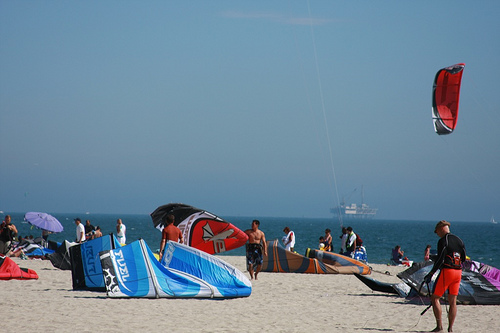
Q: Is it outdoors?
A: Yes, it is outdoors.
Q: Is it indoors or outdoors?
A: It is outdoors.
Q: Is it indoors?
A: No, it is outdoors.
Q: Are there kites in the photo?
A: Yes, there is a kite.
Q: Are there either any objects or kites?
A: Yes, there is a kite.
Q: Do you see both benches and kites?
A: No, there is a kite but no benches.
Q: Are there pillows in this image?
A: No, there are no pillows.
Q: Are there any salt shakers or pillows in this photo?
A: No, there are no pillows or salt shakers.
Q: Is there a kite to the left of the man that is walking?
A: Yes, there is a kite to the left of the man.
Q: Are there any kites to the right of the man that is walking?
A: No, the kite is to the left of the man.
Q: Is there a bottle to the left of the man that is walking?
A: No, there is a kite to the left of the man.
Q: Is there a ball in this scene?
A: No, there are no balls.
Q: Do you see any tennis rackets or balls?
A: No, there are no balls or tennis rackets.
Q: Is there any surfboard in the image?
A: No, there are no surfboards.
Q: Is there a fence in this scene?
A: No, there are no fences.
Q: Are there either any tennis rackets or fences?
A: No, there are no fences or tennis rackets.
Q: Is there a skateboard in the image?
A: No, there are no skateboards.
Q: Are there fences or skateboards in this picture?
A: No, there are no skateboards or fences.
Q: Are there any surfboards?
A: No, there are no surfboards.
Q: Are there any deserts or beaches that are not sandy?
A: No, there is a beach but it is sandy.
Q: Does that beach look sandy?
A: Yes, the beach is sandy.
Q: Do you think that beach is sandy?
A: Yes, the beach is sandy.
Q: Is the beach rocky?
A: No, the beach is sandy.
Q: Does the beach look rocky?
A: No, the beach is sandy.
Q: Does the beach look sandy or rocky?
A: The beach is sandy.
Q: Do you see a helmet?
A: No, there are no helmets.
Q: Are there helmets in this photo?
A: No, there are no helmets.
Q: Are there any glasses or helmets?
A: No, there are no helmets or glasses.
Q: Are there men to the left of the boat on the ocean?
A: Yes, there is a man to the left of the boat.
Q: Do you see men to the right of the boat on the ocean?
A: No, the man is to the left of the boat.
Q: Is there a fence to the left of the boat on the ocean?
A: No, there is a man to the left of the boat.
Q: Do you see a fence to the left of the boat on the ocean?
A: No, there is a man to the left of the boat.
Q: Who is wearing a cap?
A: The man is wearing a cap.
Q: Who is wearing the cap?
A: The man is wearing a cap.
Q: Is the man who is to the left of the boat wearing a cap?
A: Yes, the man is wearing a cap.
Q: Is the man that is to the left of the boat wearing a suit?
A: No, the man is wearing a cap.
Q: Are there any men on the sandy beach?
A: Yes, there is a man on the beach.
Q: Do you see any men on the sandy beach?
A: Yes, there is a man on the beach.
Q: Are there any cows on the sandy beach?
A: No, there is a man on the beach.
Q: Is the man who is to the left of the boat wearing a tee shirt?
A: Yes, the man is wearing a tee shirt.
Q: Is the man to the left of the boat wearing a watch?
A: No, the man is wearing a tee shirt.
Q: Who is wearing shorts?
A: The man is wearing shorts.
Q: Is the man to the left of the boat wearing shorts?
A: Yes, the man is wearing shorts.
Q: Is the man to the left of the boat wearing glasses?
A: No, the man is wearing shorts.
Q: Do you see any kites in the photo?
A: Yes, there is a kite.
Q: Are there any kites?
A: Yes, there is a kite.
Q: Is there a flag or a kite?
A: Yes, there is a kite.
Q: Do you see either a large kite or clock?
A: Yes, there is a large kite.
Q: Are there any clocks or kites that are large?
A: Yes, the kite is large.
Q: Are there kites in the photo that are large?
A: Yes, there is a large kite.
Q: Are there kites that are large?
A: Yes, there is a kite that is large.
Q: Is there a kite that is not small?
A: Yes, there is a large kite.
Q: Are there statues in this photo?
A: No, there are no statues.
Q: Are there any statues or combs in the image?
A: No, there are no statues or combs.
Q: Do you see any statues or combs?
A: No, there are no statues or combs.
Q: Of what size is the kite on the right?
A: The kite is large.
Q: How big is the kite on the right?
A: The kite is large.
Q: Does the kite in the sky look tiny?
A: No, the kite is large.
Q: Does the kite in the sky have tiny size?
A: No, the kite is large.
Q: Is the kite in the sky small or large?
A: The kite is large.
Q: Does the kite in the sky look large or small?
A: The kite is large.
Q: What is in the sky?
A: The kite is in the sky.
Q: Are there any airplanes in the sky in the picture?
A: No, there is a kite in the sky.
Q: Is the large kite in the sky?
A: Yes, the kite is in the sky.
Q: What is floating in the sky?
A: The kite is floating in the sky.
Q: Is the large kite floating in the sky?
A: Yes, the kite is floating in the sky.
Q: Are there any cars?
A: No, there are no cars.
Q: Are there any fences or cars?
A: No, there are no cars or fences.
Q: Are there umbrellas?
A: Yes, there is an umbrella.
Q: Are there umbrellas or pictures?
A: Yes, there is an umbrella.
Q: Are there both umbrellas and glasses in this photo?
A: No, there is an umbrella but no glasses.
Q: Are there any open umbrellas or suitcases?
A: Yes, there is an open umbrella.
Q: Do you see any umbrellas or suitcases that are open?
A: Yes, the umbrella is open.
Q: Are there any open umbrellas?
A: Yes, there is an open umbrella.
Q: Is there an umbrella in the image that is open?
A: Yes, there is an umbrella that is open.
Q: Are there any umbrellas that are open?
A: Yes, there is an umbrella that is open.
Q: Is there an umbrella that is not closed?
A: Yes, there is a open umbrella.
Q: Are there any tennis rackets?
A: No, there are no tennis rackets.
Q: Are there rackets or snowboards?
A: No, there are no rackets or snowboards.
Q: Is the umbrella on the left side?
A: Yes, the umbrella is on the left of the image.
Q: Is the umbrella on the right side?
A: No, the umbrella is on the left of the image.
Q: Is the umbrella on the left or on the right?
A: The umbrella is on the left of the image.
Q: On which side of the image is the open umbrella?
A: The umbrella is on the left of the image.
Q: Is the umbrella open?
A: Yes, the umbrella is open.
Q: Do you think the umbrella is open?
A: Yes, the umbrella is open.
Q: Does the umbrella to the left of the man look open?
A: Yes, the umbrella is open.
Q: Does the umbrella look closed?
A: No, the umbrella is open.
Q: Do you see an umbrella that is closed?
A: No, there is an umbrella but it is open.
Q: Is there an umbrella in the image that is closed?
A: No, there is an umbrella but it is open.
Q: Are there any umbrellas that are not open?
A: No, there is an umbrella but it is open.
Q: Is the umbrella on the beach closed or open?
A: The umbrella is open.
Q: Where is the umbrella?
A: The umbrella is on the beach.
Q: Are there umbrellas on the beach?
A: Yes, there is an umbrella on the beach.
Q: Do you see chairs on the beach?
A: No, there is an umbrella on the beach.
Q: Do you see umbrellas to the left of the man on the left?
A: Yes, there is an umbrella to the left of the man.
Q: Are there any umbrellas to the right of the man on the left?
A: No, the umbrella is to the left of the man.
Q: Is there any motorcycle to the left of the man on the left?
A: No, there is an umbrella to the left of the man.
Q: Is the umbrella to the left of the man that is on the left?
A: Yes, the umbrella is to the left of the man.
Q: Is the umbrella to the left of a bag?
A: No, the umbrella is to the left of the man.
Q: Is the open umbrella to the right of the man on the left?
A: No, the umbrella is to the left of the man.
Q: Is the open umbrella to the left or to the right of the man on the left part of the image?
A: The umbrella is to the left of the man.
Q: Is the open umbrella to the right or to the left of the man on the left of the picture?
A: The umbrella is to the left of the man.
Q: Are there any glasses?
A: No, there are no glasses.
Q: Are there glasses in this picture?
A: No, there are no glasses.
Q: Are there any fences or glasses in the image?
A: No, there are no glasses or fences.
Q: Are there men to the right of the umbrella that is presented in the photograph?
A: Yes, there is a man to the right of the umbrella.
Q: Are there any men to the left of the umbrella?
A: No, the man is to the right of the umbrella.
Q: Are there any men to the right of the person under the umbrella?
A: Yes, there is a man to the right of the person.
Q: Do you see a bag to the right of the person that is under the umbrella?
A: No, there is a man to the right of the person.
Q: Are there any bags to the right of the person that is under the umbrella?
A: No, there is a man to the right of the person.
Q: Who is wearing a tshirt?
A: The man is wearing a tshirt.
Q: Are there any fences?
A: No, there are no fences.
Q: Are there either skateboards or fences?
A: No, there are no fences or skateboards.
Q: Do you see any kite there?
A: Yes, there is a kite.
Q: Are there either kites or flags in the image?
A: Yes, there is a kite.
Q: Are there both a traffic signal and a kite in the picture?
A: No, there is a kite but no traffic lights.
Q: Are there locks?
A: No, there are no locks.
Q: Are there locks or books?
A: No, there are no locks or books.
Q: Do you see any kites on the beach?
A: Yes, there is a kite on the beach.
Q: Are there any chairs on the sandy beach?
A: No, there is a kite on the beach.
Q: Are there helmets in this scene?
A: No, there are no helmets.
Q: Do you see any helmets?
A: No, there are no helmets.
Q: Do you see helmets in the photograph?
A: No, there are no helmets.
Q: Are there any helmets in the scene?
A: No, there are no helmets.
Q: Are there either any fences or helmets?
A: No, there are no helmets or fences.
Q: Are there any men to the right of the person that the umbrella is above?
A: Yes, there is a man to the right of the person.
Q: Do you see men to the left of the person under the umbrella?
A: No, the man is to the right of the person.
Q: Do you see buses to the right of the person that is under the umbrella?
A: No, there is a man to the right of the person.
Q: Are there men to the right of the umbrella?
A: Yes, there is a man to the right of the umbrella.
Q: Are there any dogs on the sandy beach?
A: No, there is a man on the beach.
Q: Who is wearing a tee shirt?
A: The man is wearing a tee shirt.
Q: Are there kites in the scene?
A: Yes, there is a kite.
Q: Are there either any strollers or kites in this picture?
A: Yes, there is a kite.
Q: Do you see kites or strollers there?
A: Yes, there is a kite.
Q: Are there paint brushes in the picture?
A: No, there are no paint brushes.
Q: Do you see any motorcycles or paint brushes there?
A: No, there are no paint brushes or motorcycles.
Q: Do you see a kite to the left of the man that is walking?
A: Yes, there is a kite to the left of the man.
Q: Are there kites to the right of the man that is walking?
A: No, the kite is to the left of the man.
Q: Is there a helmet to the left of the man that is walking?
A: No, there is a kite to the left of the man.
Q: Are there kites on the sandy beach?
A: Yes, there is a kite on the beach.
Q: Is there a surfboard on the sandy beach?
A: No, there is a kite on the beach.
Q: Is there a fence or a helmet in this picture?
A: No, there are no helmets or fences.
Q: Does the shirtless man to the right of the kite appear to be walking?
A: Yes, the man is walking.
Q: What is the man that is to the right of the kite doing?
A: The man is walking.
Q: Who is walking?
A: The man is walking.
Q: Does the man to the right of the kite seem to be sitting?
A: No, the man is walking.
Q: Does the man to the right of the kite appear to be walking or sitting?
A: The man is walking.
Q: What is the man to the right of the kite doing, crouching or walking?
A: The man is walking.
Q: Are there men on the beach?
A: Yes, there is a man on the beach.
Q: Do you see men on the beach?
A: Yes, there is a man on the beach.